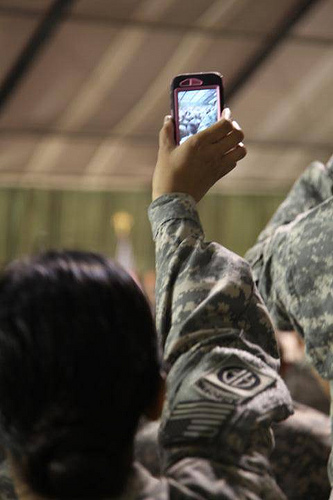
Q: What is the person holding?
A: A cellphone.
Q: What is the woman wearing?
A: A military uniform.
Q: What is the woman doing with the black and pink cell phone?
A: Taking a picture.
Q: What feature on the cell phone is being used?
A: A camera.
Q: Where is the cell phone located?
A: In a person's hand.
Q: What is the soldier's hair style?
A: A bun.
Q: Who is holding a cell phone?
A: A female soldier.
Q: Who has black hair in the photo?
A: The female soldier.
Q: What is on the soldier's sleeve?
A: Patches.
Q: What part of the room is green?
A: The wall.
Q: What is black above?
A: Pole.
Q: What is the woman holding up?
A: Her cell phone.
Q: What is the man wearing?
A: Army uniform.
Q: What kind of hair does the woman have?
A: Dark.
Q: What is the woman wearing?
A: Camouflage.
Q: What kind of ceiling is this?
A: Light colored.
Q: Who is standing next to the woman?
A: A person in camouflage.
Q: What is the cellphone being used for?
A: Take a picture.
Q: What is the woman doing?
A: Taking a photo.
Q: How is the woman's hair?
A: In a bun.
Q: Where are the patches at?
A: On a sleeve.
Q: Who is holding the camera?
A: Woman in uniform.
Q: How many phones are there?
A: One.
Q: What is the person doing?
A: Recording other people.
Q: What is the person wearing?
A: A military uniform.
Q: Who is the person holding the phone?
A: A woman.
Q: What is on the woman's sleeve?
A: Patches.